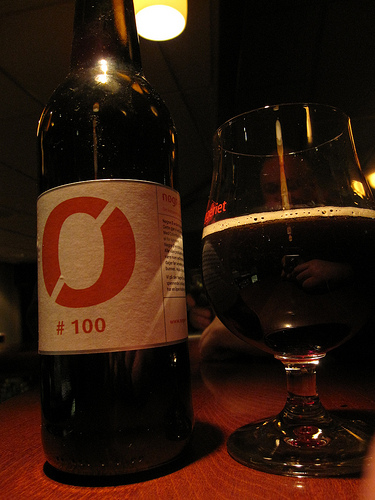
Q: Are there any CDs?
A: No, there are no cds.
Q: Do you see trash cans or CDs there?
A: No, there are no CDs or trash cans.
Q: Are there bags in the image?
A: No, there are no bags.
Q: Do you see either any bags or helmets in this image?
A: No, there are no bags or helmets.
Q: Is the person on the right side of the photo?
A: Yes, the person is on the right of the image.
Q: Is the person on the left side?
A: No, the person is on the right of the image.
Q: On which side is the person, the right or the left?
A: The person is on the right of the image.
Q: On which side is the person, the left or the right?
A: The person is on the right of the image.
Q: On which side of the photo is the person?
A: The person is on the right of the image.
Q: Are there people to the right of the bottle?
A: Yes, there is a person to the right of the bottle.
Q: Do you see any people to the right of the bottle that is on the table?
A: Yes, there is a person to the right of the bottle.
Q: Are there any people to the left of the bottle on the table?
A: No, the person is to the right of the bottle.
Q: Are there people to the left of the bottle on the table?
A: No, the person is to the right of the bottle.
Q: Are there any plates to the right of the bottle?
A: No, there is a person to the right of the bottle.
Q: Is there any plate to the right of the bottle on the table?
A: No, there is a person to the right of the bottle.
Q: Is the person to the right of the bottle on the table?
A: Yes, the person is to the right of the bottle.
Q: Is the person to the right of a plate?
A: No, the person is to the right of the bottle.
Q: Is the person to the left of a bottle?
A: No, the person is to the right of a bottle.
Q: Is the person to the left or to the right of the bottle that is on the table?
A: The person is to the right of the bottle.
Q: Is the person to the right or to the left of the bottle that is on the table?
A: The person is to the right of the bottle.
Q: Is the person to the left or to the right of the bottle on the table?
A: The person is to the right of the bottle.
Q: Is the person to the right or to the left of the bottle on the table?
A: The person is to the right of the bottle.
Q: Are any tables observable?
A: Yes, there is a table.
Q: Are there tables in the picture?
A: Yes, there is a table.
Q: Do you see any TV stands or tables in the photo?
A: Yes, there is a table.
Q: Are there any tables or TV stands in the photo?
A: Yes, there is a table.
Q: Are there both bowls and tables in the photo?
A: No, there is a table but no bowls.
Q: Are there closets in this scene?
A: No, there are no closets.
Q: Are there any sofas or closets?
A: No, there are no closets or sofas.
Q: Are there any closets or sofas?
A: No, there are no closets or sofas.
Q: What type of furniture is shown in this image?
A: The furniture is a table.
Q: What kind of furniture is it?
A: The piece of furniture is a table.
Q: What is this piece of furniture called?
A: That is a table.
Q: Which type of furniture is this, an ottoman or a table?
A: That is a table.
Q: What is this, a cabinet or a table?
A: This is a table.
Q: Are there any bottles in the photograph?
A: Yes, there is a bottle.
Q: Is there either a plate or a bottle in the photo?
A: Yes, there is a bottle.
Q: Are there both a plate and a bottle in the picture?
A: No, there is a bottle but no plates.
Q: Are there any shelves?
A: No, there are no shelves.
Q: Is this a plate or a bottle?
A: This is a bottle.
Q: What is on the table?
A: The bottle is on the table.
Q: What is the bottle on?
A: The bottle is on the table.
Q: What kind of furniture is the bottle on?
A: The bottle is on the table.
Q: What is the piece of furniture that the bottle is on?
A: The piece of furniture is a table.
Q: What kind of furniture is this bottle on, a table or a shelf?
A: The bottle is on a table.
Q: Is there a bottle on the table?
A: Yes, there is a bottle on the table.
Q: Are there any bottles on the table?
A: Yes, there is a bottle on the table.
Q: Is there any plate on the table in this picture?
A: No, there is a bottle on the table.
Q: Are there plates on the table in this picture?
A: No, there is a bottle on the table.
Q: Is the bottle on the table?
A: Yes, the bottle is on the table.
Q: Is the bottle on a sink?
A: No, the bottle is on the table.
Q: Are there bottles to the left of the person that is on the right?
A: Yes, there is a bottle to the left of the person.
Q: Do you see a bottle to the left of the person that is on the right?
A: Yes, there is a bottle to the left of the person.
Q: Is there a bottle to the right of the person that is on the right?
A: No, the bottle is to the left of the person.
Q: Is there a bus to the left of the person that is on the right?
A: No, there is a bottle to the left of the person.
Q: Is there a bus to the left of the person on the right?
A: No, there is a bottle to the left of the person.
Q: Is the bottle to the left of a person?
A: Yes, the bottle is to the left of a person.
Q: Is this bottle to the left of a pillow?
A: No, the bottle is to the left of a person.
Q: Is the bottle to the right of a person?
A: No, the bottle is to the left of a person.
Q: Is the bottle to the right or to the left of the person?
A: The bottle is to the left of the person.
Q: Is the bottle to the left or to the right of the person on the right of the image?
A: The bottle is to the left of the person.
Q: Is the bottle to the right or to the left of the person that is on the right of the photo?
A: The bottle is to the left of the person.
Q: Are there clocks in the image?
A: No, there are no clocks.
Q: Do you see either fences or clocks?
A: No, there are no clocks or fences.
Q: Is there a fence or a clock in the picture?
A: No, there are no clocks or fences.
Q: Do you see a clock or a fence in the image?
A: No, there are no clocks or fences.